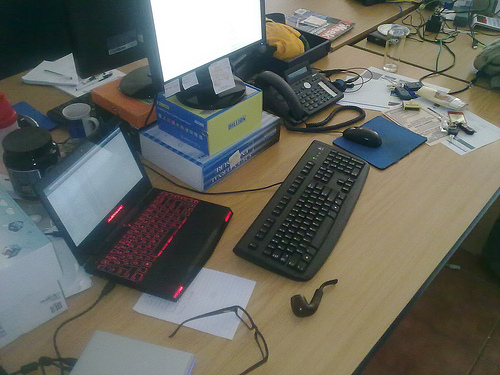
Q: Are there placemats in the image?
A: No, there are no placemats.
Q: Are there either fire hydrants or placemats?
A: No, there are no placemats or fire hydrants.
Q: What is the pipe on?
A: The pipe is on the desk.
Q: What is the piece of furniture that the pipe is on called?
A: The piece of furniture is a desk.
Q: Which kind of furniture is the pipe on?
A: The pipe is on the desk.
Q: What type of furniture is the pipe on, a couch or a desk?
A: The pipe is on a desk.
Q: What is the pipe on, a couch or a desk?
A: The pipe is on a desk.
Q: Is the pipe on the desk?
A: Yes, the pipe is on the desk.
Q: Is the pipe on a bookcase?
A: No, the pipe is on the desk.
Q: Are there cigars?
A: No, there are no cigars.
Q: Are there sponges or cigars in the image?
A: No, there are no cigars or sponges.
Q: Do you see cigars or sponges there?
A: No, there are no cigars or sponges.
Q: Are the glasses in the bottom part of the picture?
A: Yes, the glasses are in the bottom of the image.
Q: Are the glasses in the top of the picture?
A: No, the glasses are in the bottom of the image.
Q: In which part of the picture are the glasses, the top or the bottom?
A: The glasses are in the bottom of the image.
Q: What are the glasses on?
A: The glasses are on the desk.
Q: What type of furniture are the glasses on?
A: The glasses are on the desk.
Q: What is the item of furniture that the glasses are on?
A: The piece of furniture is a desk.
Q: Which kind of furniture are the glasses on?
A: The glasses are on the desk.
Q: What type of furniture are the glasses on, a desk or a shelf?
A: The glasses are on a desk.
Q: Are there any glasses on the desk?
A: Yes, there are glasses on the desk.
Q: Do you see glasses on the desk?
A: Yes, there are glasses on the desk.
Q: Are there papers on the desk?
A: No, there are glasses on the desk.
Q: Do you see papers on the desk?
A: No, there are glasses on the desk.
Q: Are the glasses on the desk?
A: Yes, the glasses are on the desk.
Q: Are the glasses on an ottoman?
A: No, the glasses are on the desk.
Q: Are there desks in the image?
A: Yes, there is a desk.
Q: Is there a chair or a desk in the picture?
A: Yes, there is a desk.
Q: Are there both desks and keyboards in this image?
A: Yes, there are both a desk and a keyboard.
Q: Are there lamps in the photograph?
A: No, there are no lamps.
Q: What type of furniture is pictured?
A: The furniture is a desk.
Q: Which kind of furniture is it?
A: The piece of furniture is a desk.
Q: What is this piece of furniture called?
A: This is a desk.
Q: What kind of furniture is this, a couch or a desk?
A: This is a desk.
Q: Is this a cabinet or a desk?
A: This is a desk.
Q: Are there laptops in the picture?
A: Yes, there is a laptop.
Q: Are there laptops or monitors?
A: Yes, there is a laptop.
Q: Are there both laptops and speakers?
A: No, there is a laptop but no speakers.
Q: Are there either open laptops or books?
A: Yes, there is an open laptop.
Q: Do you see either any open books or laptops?
A: Yes, there is an open laptop.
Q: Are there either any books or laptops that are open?
A: Yes, the laptop is open.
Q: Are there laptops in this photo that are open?
A: Yes, there is an open laptop.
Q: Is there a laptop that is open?
A: Yes, there is a laptop that is open.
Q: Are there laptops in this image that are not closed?
A: Yes, there is a open laptop.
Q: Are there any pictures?
A: No, there are no pictures.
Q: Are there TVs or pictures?
A: No, there are no pictures or tvs.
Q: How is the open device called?
A: The device is a laptop.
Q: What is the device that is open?
A: The device is a laptop.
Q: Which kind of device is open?
A: The device is a laptop.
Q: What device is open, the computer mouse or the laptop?
A: The laptop is open.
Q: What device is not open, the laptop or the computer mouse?
A: The computer mouse is not open.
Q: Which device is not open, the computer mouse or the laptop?
A: The computer mouse is not open.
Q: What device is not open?
A: The device is a computer mouse.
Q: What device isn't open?
A: The device is a computer mouse.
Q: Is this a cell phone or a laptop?
A: This is a laptop.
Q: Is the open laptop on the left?
A: Yes, the laptop is on the left of the image.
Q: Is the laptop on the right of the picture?
A: No, the laptop is on the left of the image.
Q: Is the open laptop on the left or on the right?
A: The laptop is on the left of the image.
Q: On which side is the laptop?
A: The laptop is on the left of the image.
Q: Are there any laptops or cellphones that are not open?
A: No, there is a laptop but it is open.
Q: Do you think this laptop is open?
A: Yes, the laptop is open.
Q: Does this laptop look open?
A: Yes, the laptop is open.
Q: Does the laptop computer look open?
A: Yes, the laptop computer is open.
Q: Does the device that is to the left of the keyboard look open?
A: Yes, the laptop computer is open.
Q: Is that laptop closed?
A: No, the laptop is open.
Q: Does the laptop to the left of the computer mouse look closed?
A: No, the laptop is open.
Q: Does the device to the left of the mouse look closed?
A: No, the laptop is open.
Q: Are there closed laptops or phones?
A: No, there is a laptop but it is open.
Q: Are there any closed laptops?
A: No, there is a laptop but it is open.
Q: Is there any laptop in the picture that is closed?
A: No, there is a laptop but it is open.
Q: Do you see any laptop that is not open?
A: No, there is a laptop but it is open.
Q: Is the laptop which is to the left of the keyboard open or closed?
A: The laptop is open.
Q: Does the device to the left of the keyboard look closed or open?
A: The laptop is open.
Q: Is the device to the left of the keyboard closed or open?
A: The laptop is open.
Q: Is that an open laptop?
A: Yes, that is an open laptop.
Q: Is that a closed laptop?
A: No, that is an open laptop.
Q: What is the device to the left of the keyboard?
A: The device is a laptop.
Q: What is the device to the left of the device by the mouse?
A: The device is a laptop.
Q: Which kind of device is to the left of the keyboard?
A: The device is a laptop.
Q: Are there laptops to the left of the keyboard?
A: Yes, there is a laptop to the left of the keyboard.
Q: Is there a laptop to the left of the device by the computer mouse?
A: Yes, there is a laptop to the left of the keyboard.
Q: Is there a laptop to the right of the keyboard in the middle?
A: No, the laptop is to the left of the keyboard.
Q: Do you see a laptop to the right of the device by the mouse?
A: No, the laptop is to the left of the keyboard.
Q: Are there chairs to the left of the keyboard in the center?
A: No, there is a laptop to the left of the keyboard.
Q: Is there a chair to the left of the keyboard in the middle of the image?
A: No, there is a laptop to the left of the keyboard.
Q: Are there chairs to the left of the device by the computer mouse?
A: No, there is a laptop to the left of the keyboard.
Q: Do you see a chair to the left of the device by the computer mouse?
A: No, there is a laptop to the left of the keyboard.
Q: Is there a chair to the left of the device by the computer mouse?
A: No, there is a laptop to the left of the keyboard.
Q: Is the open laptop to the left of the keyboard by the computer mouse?
A: Yes, the laptop is to the left of the keyboard.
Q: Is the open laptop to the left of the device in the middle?
A: Yes, the laptop is to the left of the keyboard.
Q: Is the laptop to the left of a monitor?
A: No, the laptop is to the left of the keyboard.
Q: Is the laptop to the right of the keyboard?
A: No, the laptop is to the left of the keyboard.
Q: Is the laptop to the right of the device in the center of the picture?
A: No, the laptop is to the left of the keyboard.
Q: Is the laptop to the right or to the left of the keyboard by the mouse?
A: The laptop is to the left of the keyboard.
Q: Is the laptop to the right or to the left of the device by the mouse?
A: The laptop is to the left of the keyboard.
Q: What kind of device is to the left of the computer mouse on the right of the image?
A: The device is a laptop.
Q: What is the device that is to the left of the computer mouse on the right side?
A: The device is a laptop.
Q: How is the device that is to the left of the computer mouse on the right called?
A: The device is a laptop.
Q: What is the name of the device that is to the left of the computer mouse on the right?
A: The device is a laptop.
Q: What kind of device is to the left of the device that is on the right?
A: The device is a laptop.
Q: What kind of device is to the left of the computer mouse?
A: The device is a laptop.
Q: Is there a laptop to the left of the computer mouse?
A: Yes, there is a laptop to the left of the computer mouse.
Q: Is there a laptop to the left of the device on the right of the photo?
A: Yes, there is a laptop to the left of the computer mouse.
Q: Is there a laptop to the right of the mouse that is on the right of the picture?
A: No, the laptop is to the left of the mouse.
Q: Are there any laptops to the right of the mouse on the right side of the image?
A: No, the laptop is to the left of the mouse.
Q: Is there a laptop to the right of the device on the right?
A: No, the laptop is to the left of the mouse.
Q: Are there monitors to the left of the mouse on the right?
A: No, there is a laptop to the left of the mouse.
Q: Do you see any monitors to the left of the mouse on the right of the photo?
A: No, there is a laptop to the left of the mouse.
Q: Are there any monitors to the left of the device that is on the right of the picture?
A: No, there is a laptop to the left of the mouse.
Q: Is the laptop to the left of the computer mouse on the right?
A: Yes, the laptop is to the left of the computer mouse.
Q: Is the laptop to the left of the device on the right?
A: Yes, the laptop is to the left of the computer mouse.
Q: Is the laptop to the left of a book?
A: No, the laptop is to the left of the computer mouse.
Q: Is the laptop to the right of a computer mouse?
A: No, the laptop is to the left of a computer mouse.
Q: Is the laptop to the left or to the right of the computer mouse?
A: The laptop is to the left of the computer mouse.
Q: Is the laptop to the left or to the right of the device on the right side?
A: The laptop is to the left of the computer mouse.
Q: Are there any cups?
A: Yes, there is a cup.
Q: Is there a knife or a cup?
A: Yes, there is a cup.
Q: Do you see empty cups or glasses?
A: Yes, there is an empty cup.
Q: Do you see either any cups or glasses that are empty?
A: Yes, the cup is empty.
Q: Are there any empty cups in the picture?
A: Yes, there is an empty cup.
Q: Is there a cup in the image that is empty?
A: Yes, there is a cup that is empty.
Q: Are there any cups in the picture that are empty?
A: Yes, there is a cup that is empty.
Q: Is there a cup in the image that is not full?
A: Yes, there is a empty cup.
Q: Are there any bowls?
A: No, there are no bowls.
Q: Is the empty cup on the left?
A: Yes, the cup is on the left of the image.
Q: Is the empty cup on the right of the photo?
A: No, the cup is on the left of the image.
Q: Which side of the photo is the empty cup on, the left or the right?
A: The cup is on the left of the image.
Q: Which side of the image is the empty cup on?
A: The cup is on the left of the image.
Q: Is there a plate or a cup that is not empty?
A: No, there is a cup but it is empty.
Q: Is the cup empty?
A: Yes, the cup is empty.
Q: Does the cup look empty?
A: Yes, the cup is empty.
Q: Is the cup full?
A: No, the cup is empty.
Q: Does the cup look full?
A: No, the cup is empty.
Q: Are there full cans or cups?
A: No, there is a cup but it is empty.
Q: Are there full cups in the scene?
A: No, there is a cup but it is empty.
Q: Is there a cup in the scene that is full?
A: No, there is a cup but it is empty.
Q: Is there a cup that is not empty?
A: No, there is a cup but it is empty.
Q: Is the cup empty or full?
A: The cup is empty.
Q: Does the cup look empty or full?
A: The cup is empty.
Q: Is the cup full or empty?
A: The cup is empty.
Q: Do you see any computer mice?
A: Yes, there is a computer mouse.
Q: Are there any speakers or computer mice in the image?
A: Yes, there is a computer mouse.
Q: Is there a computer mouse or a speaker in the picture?
A: Yes, there is a computer mouse.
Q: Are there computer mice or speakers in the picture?
A: Yes, there is a computer mouse.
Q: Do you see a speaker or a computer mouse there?
A: Yes, there is a computer mouse.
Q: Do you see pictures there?
A: No, there are no pictures.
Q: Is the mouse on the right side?
A: Yes, the mouse is on the right of the image.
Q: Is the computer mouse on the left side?
A: No, the computer mouse is on the right of the image.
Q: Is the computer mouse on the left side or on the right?
A: The computer mouse is on the right of the image.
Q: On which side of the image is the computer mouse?
A: The computer mouse is on the right of the image.